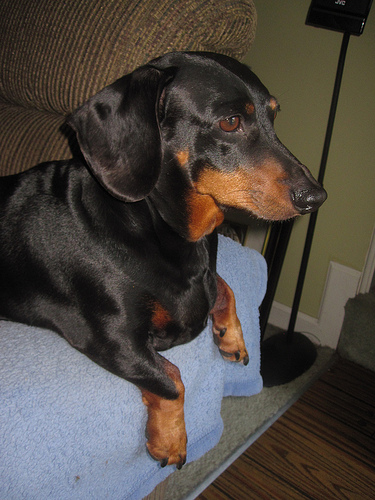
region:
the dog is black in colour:
[0, 15, 319, 466]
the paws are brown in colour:
[114, 273, 315, 444]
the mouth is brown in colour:
[167, 89, 343, 267]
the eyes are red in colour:
[185, 83, 248, 157]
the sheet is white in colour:
[32, 390, 110, 477]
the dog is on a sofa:
[22, 7, 347, 439]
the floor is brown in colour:
[259, 446, 372, 487]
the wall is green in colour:
[296, 24, 311, 117]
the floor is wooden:
[252, 454, 347, 499]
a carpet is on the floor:
[202, 395, 293, 448]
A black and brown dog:
[7, 119, 307, 407]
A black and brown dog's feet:
[101, 338, 200, 479]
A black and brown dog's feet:
[207, 267, 255, 369]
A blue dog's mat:
[8, 378, 129, 480]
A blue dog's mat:
[182, 352, 231, 423]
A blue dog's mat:
[229, 247, 261, 333]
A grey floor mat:
[165, 458, 214, 498]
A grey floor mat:
[223, 398, 254, 439]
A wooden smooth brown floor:
[279, 432, 329, 494]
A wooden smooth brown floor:
[317, 397, 363, 476]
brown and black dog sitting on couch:
[1, 45, 350, 466]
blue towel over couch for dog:
[6, 225, 274, 489]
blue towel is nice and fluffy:
[291, 175, 330, 209]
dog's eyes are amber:
[219, 108, 250, 133]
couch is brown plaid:
[3, 0, 264, 171]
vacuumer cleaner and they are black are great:
[289, 0, 364, 330]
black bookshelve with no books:
[216, 201, 302, 321]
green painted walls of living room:
[236, 2, 374, 347]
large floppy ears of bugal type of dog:
[60, 60, 174, 192]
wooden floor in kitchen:
[195, 347, 369, 494]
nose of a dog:
[279, 174, 340, 221]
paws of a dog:
[121, 277, 249, 474]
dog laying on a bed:
[0, 44, 332, 473]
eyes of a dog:
[200, 96, 289, 142]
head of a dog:
[76, 48, 332, 241]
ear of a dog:
[50, 54, 168, 209]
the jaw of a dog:
[200, 121, 331, 226]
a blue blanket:
[0, 221, 283, 499]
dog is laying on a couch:
[0, 48, 340, 468]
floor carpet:
[101, 323, 337, 497]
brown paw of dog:
[211, 265, 266, 379]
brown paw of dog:
[142, 351, 209, 479]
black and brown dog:
[10, 15, 333, 480]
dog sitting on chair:
[8, 0, 342, 411]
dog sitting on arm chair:
[1, 248, 354, 467]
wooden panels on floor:
[236, 411, 372, 497]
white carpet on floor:
[229, 392, 257, 429]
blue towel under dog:
[1, 226, 318, 444]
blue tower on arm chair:
[1, 217, 328, 498]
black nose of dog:
[290, 156, 327, 224]